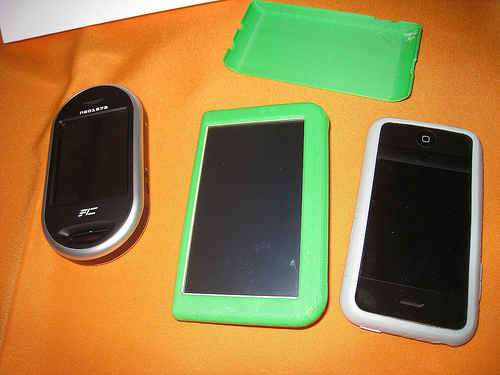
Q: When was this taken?
A: During the day.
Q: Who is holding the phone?
A: No one.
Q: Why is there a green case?
A: To protect the phone.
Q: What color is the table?
A: Orange.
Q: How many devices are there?
A: Three.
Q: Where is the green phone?
A: In the middle.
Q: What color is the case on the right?
A: White.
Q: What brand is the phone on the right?
A: Apple.